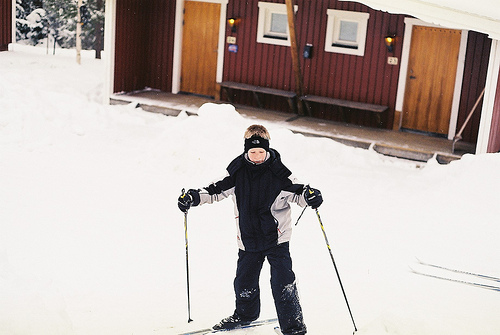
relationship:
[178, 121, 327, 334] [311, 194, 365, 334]
boy preparing to ski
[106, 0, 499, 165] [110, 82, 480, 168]
building next to porch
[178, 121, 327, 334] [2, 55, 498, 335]
boy skis on snow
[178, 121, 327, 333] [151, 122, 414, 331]
boy on ski's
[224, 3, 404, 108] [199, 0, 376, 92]
siding on building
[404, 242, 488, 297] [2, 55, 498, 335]
ski poles laying in snow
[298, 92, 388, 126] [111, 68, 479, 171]
bench on porch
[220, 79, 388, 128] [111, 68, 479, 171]
two benches on porch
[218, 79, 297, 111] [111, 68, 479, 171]
bench on porch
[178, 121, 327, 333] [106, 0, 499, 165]
boy in front of building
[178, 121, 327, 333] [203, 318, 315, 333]
boy watching step